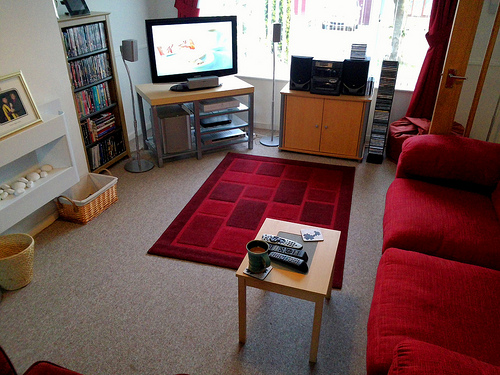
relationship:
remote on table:
[260, 230, 305, 249] [233, 202, 344, 365]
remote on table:
[265, 242, 312, 260] [233, 202, 344, 365]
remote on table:
[271, 250, 310, 279] [233, 202, 344, 365]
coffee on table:
[245, 238, 274, 274] [233, 202, 344, 365]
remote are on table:
[261, 233, 303, 250] [233, 202, 344, 365]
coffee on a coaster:
[245, 238, 274, 274] [245, 268, 274, 279]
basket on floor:
[51, 171, 126, 223] [57, 224, 149, 349]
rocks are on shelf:
[10, 174, 36, 195] [2, 135, 74, 206]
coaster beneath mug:
[245, 268, 274, 279] [238, 228, 274, 285]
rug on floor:
[142, 146, 363, 290] [57, 224, 149, 349]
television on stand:
[146, 13, 241, 86] [137, 74, 258, 150]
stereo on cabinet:
[283, 45, 379, 106] [275, 76, 371, 162]